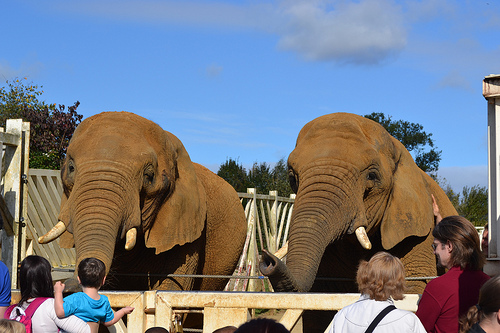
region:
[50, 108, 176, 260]
the head of an elephant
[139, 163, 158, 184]
the eye of an elephant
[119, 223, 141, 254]
the tusk of an elephant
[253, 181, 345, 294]
the trunk of an elephant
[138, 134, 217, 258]
the ear of an elephant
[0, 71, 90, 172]
a green leafy tree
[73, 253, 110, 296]
the head of a child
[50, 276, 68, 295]
the hand of a child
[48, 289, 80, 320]
the arm of a child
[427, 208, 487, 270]
the head of a woman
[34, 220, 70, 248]
white ivory elephant tusk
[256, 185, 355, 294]
trunk of brown elephant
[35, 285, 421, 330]
white metal gate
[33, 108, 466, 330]
two adult elephants standing side by side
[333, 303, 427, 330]
black bag strap over persons shoulder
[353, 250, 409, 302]
brown medium length wavy hair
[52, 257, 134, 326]
back of dark haired young boy wearing blue shirt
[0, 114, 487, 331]
white metal fence with diagonal slats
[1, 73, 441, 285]
tress located behind fence holding in elephants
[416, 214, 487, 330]
man wearing glasses and a maroon colored shirt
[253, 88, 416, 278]
A big cute elephant holding up its trunk.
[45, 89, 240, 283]
Another elephant in the zoo.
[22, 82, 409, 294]
Two elephants just chilling in a zoo.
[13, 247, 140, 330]
A momma and a kid looking at the elephants.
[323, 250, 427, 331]
A ginger boy looking at the elephants too.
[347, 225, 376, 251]
An elephants tusk still on the elephant.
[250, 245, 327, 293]
The tip of elephants' trunk.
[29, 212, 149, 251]
An elephants' tusk and trunk.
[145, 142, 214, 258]
An elephants' giant ear.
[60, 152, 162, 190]
An elephants' dark brown eyes.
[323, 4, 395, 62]
part of a cloud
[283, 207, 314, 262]
part of a trunk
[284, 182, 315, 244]
part of a trunk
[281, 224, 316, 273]
part of a trunk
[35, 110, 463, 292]
Two big gray elephants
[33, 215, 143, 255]
Two white tusks on an elephant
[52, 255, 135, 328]
Boy wearing a blue shirt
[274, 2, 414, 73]
A white cloud in the sky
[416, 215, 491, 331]
Person wearing a red shirt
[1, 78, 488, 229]
Trees with green leaves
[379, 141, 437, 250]
A big ear on an elephant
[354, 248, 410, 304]
Blonde hair on woman's head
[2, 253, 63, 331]
Woman wearing a pink backpack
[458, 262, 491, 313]
A shadow on red shirt